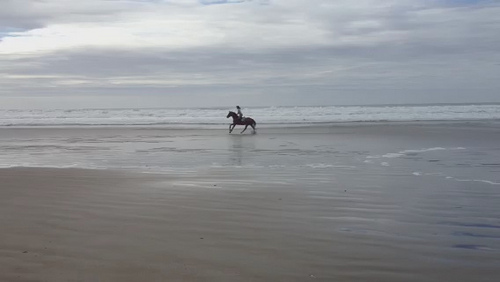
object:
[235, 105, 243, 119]
woman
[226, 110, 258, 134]
horse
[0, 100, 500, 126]
foam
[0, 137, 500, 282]
beach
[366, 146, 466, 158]
froth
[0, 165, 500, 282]
hitting sand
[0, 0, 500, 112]
sky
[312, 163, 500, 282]
ripples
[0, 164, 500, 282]
shore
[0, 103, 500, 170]
water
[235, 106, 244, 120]
person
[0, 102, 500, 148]
waves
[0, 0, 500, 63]
cloud